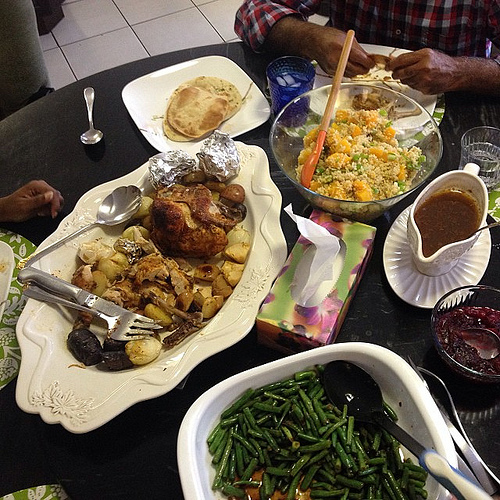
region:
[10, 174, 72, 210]
person's hand on table top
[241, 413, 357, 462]
green beans in white bowl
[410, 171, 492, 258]
bowl of brown gravy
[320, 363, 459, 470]
large black and gray spoon in bowl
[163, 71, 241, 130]
naan bread on plate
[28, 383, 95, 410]
beautiful design on edge of white plate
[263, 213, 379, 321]
box of white tissue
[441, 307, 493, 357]
cranberry sauce in clear bowl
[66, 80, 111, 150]
small silver spoon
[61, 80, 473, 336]
black table filled with food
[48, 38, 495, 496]
Family members having a feast.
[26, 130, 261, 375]
Family members eating chicken and potatoes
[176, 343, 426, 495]
Family members eating string beans.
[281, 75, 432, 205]
Family members eating quinoa.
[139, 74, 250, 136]
Family members eating bread.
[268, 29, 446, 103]
Family member has beverage next to food waiting for when he finishes.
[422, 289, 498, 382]
Family members eating cranberry sauce.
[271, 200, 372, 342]
Napkins on the table for when hands get messy.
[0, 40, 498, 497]
Utensils in the food but they aren't being used.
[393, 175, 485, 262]
Gravy for the chicken.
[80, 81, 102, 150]
silver spoon on table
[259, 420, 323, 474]
green peas in a dish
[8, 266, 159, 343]
knife and fork on dish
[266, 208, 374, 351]
box of kleenex on table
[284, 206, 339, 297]
white piece of tissue in box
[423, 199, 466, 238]
brown gravy in boat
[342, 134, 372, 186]
stuffing in a bowl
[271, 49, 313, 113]
blue glass on table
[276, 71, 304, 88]
ice in blue cup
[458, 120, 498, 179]
clear glass with water on table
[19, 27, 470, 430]
a meal on the table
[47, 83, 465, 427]
a big meal for eating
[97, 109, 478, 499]
this meal has meat and vegetables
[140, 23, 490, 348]
this meal has gravy and rice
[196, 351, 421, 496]
green beans in a pot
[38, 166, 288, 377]
meat and potatoes on a tray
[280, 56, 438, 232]
some type of vegetable dish on the side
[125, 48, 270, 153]
bread on a small platter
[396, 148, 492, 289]
gravy in a cup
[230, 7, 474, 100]
this person is eating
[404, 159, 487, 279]
sauce pot on black table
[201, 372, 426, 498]
green beans on white pot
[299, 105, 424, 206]
salad inside bowl on table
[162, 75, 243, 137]
patty on white plate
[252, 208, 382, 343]
multicolored napking box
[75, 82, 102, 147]
gray metal spoon on black table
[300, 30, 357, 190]
orange wooden tablespoon cooking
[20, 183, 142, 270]
gray metal spoon on chicken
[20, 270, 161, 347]
gray metal fork and knife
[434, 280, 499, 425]
cup of grape on black table